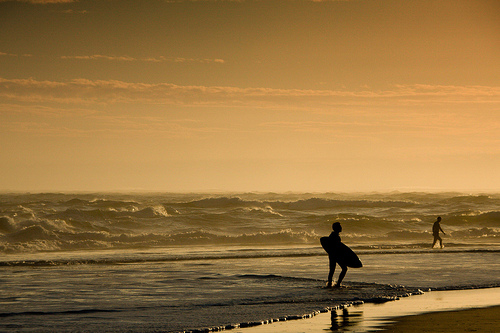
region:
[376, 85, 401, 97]
part of a cloud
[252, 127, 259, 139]
section of a cloud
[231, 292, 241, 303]
part of the sea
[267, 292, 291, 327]
part of the shore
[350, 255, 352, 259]
tip of a board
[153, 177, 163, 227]
part of the ocean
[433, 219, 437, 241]
body of a man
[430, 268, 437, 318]
part of the beach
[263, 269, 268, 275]
part of an ocean wave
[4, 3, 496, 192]
a cloudy grey sky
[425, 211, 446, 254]
a person walking through the water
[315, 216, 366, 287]
a surfboard carried in a person's arms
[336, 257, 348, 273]
a bent knee of a surfer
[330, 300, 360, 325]
the reflection of a man on wet sand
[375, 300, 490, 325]
sand past the water's dge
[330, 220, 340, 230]
the head of a surfer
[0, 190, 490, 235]
waves on the water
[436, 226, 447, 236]
an arm held in front of a person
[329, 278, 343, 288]
water splashing around a person's ankles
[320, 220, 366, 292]
surfer leaving water at sunet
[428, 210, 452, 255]
surfer leaving water at sunet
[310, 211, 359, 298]
surfer carrying board at sunset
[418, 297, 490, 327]
brown wet beach at sunset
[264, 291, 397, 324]
brown wet beach at sunset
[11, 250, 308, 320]
waves in ocean at sunset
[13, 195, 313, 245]
waves in ocean at sunset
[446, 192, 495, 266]
waves in ocean at sunset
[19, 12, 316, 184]
white clouds against sky at sunset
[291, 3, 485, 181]
white clouds against sky at sunset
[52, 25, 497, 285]
man walking with board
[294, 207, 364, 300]
man holding surfboard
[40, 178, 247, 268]
ocean waves breaking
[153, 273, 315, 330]
water rippling on shore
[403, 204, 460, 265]
person walking out of water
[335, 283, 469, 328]
wet sand on the beach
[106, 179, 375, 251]
rough water with breaking waves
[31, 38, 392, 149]
clouds in the sky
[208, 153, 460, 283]
people walking in the water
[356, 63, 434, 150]
orange color on clouds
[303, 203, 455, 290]
People on the beach.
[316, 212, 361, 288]
Man holding his surfboard.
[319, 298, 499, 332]
Water on the beach.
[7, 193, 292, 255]
Waves crashing on the shore.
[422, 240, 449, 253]
A person splashes while walking.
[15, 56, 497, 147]
Clouds in the sky.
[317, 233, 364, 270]
A surfboard.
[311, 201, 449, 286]
Silhouettes of two people.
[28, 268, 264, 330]
Ocean washing up on shore.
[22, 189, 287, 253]
Waves in the ocean.